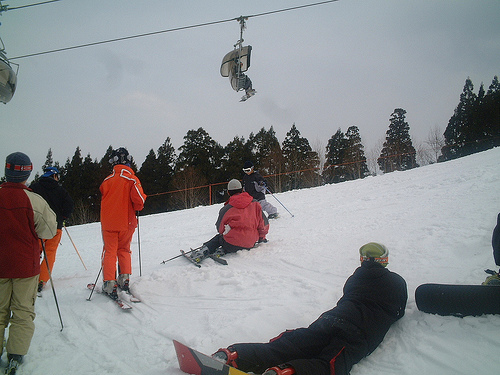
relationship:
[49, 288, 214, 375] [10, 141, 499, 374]
tracks in snow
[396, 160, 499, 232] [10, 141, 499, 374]
tracks in snow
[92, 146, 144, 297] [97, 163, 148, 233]
skier wearing jacket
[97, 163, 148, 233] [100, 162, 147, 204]
jacket has stripes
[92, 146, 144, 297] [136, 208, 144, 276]
skier holding pole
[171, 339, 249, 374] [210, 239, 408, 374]
snowboard on snowboarder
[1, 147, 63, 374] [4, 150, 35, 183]
skier wearing cap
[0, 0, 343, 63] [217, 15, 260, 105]
line for ski lift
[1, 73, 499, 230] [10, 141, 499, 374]
trees behind snow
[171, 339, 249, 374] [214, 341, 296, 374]
snowboard with boots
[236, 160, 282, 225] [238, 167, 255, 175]
skier wearing goggles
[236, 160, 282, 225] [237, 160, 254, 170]
skier wearing hat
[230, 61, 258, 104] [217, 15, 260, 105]
person on ski lift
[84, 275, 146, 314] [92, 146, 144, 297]
skis on skier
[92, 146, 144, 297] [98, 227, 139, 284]
skier wearing pants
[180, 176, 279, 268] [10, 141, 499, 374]
skier in snow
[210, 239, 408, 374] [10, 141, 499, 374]
snowboarder laying in snow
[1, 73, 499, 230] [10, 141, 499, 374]
trees by snow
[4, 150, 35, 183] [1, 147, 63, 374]
cap on skier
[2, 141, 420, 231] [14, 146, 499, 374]
fencing marks off ski area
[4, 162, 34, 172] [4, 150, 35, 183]
band on cap